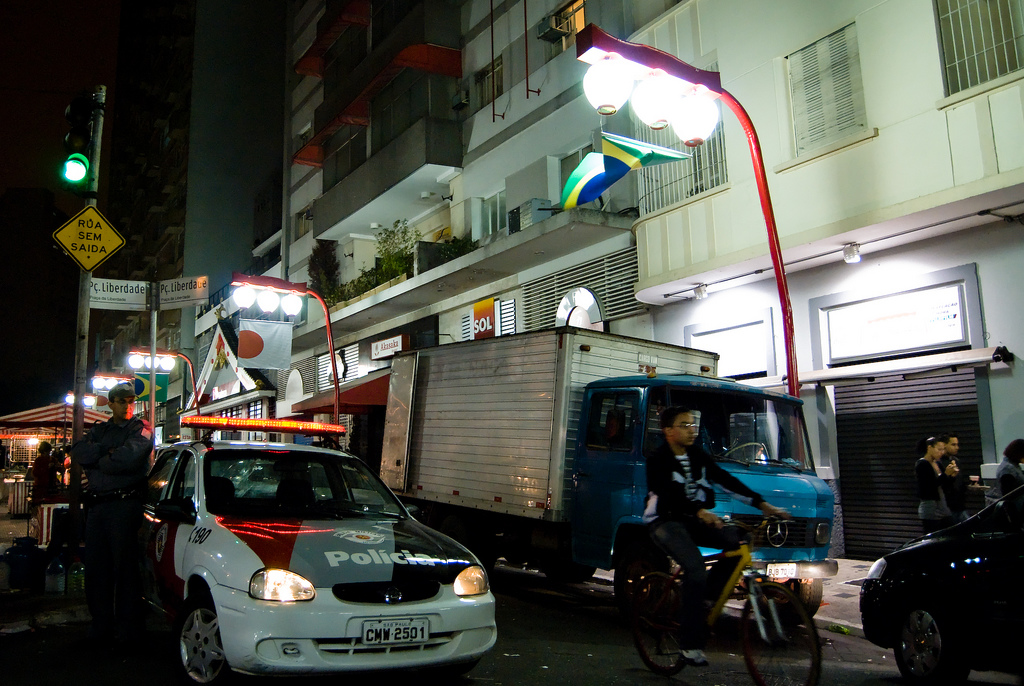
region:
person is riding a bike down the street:
[615, 416, 822, 663]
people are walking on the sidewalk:
[910, 420, 974, 525]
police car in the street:
[163, 408, 500, 683]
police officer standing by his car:
[71, 380, 164, 647]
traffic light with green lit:
[53, 86, 102, 194]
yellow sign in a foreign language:
[46, 205, 129, 273]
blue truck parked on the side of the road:
[385, 328, 831, 592]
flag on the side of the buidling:
[232, 304, 296, 372]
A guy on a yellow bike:
[593, 397, 843, 683]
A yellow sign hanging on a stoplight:
[50, 193, 136, 292]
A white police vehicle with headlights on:
[130, 379, 513, 683]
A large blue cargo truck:
[366, 315, 851, 606]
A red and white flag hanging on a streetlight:
[211, 293, 325, 393]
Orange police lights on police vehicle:
[166, 380, 378, 473]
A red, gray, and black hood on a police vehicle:
[208, 492, 502, 623]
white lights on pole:
[593, 47, 680, 187]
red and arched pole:
[631, 53, 815, 366]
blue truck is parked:
[605, 354, 859, 608]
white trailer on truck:
[371, 322, 625, 523]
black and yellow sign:
[73, 234, 146, 286]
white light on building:
[804, 222, 947, 330]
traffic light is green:
[32, 105, 134, 189]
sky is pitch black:
[26, 12, 181, 169]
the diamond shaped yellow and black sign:
[52, 199, 123, 264]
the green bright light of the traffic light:
[55, 143, 95, 181]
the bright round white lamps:
[576, 48, 720, 144]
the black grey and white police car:
[119, 433, 499, 671]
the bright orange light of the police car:
[177, 405, 346, 440]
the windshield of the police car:
[203, 437, 409, 529]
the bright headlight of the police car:
[247, 570, 308, 602]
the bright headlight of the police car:
[446, 556, 497, 601]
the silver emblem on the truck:
[762, 510, 792, 545]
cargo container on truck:
[371, 331, 710, 524]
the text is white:
[315, 545, 434, 568]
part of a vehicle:
[240, 549, 323, 607]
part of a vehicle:
[446, 556, 497, 601]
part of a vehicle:
[166, 581, 252, 683]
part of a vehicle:
[205, 442, 402, 528]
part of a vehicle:
[133, 439, 179, 504]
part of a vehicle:
[166, 445, 195, 502]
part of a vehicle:
[581, 366, 639, 455]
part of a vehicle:
[653, 388, 818, 469]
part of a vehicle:
[885, 600, 955, 678]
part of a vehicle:
[859, 553, 897, 585]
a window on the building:
[751, 44, 887, 199]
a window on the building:
[945, 10, 1022, 84]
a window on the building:
[606, 72, 778, 254]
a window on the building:
[480, 50, 537, 124]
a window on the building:
[465, 186, 513, 237]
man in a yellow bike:
[590, 391, 828, 671]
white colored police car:
[111, 395, 510, 661]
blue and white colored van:
[378, 319, 821, 588]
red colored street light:
[573, 26, 850, 616]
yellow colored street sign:
[57, 189, 131, 281]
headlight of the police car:
[254, 544, 319, 621]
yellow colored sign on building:
[456, 290, 499, 349]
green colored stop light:
[42, 138, 91, 192]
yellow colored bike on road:
[612, 499, 856, 681]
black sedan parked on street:
[827, 402, 1021, 669]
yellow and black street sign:
[53, 203, 118, 273]